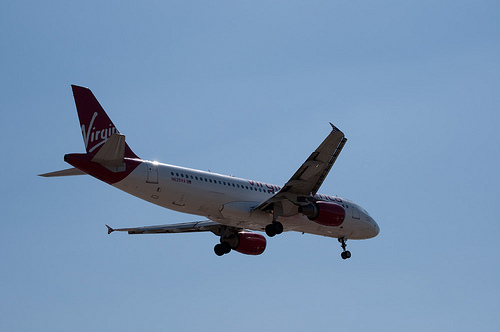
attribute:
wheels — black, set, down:
[264, 220, 284, 237]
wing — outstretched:
[255, 121, 347, 212]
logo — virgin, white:
[80, 111, 119, 154]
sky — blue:
[0, 1, 498, 331]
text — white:
[81, 112, 120, 152]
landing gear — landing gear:
[266, 206, 283, 238]